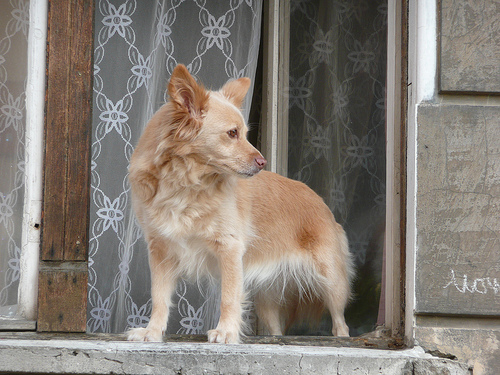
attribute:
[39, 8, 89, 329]
panel — wood, dark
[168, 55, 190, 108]
ear — brown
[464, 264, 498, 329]
graffiti — white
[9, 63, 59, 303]
pole — white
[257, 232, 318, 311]
hair — white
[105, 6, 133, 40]
flower — white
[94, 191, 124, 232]
flower — white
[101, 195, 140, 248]
flower — white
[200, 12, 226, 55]
flower — white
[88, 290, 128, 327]
flower — white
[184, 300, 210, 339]
flower — white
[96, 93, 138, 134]
flower — white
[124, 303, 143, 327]
flower — white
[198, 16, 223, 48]
flower — white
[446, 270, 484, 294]
writing — white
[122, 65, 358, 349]
dog — small, tan, red, white, brown and white, brown, clean, beautiful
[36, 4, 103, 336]
beam — tall, dark brown, wooden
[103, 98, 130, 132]
flower design — white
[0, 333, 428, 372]
ledge — concrete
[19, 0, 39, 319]
edging — white, wooden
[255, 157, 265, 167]
nose — small, brown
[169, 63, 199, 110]
ear — fluffy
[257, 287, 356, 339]
legs — back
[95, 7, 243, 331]
curtain — white, lace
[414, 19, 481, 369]
siding — gray, brick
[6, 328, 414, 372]
ledge — gray, cement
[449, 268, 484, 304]
writing — white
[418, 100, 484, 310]
brick — gray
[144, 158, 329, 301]
hair — long, blonde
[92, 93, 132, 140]
flower design — white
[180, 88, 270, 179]
head — turned sideways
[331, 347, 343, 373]
crack — black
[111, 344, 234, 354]
crack — black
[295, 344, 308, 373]
crack — black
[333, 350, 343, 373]
crack — black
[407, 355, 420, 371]
crack — black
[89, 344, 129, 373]
crack — black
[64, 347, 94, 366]
crack — black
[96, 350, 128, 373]
crack — black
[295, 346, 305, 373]
crack — black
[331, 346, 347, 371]
crack — black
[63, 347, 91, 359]
crack — black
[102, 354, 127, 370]
crack — black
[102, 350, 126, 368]
crack — black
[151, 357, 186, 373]
crack — black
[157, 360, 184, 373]
crack — black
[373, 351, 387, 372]
crack — black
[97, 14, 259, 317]
curtains — white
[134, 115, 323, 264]
fur — brown